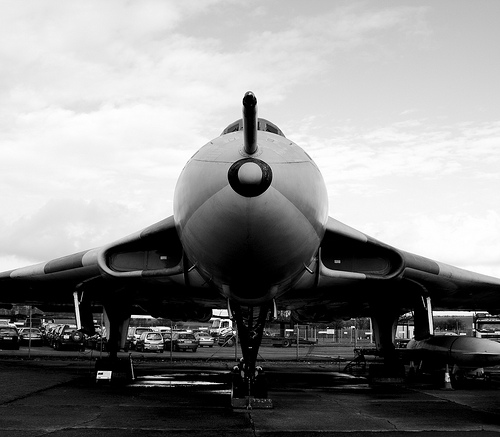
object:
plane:
[0, 92, 499, 408]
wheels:
[202, 365, 295, 398]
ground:
[3, 360, 500, 433]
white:
[152, 149, 341, 211]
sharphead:
[207, 76, 305, 218]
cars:
[171, 329, 199, 350]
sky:
[30, 17, 486, 80]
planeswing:
[326, 220, 500, 318]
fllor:
[133, 369, 226, 404]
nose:
[243, 91, 257, 151]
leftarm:
[0, 216, 189, 314]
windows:
[224, 111, 295, 134]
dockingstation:
[18, 330, 497, 396]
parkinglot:
[0, 321, 313, 354]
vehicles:
[142, 323, 198, 351]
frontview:
[432, 313, 482, 339]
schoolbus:
[391, 313, 490, 336]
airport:
[0, 240, 500, 436]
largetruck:
[212, 319, 292, 347]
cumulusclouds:
[50, 9, 221, 101]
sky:
[358, 44, 488, 97]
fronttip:
[241, 90, 258, 112]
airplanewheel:
[233, 376, 283, 409]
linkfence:
[160, 329, 208, 363]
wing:
[337, 226, 475, 288]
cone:
[442, 365, 453, 391]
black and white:
[2, 2, 499, 369]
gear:
[228, 362, 263, 408]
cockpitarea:
[217, 93, 288, 132]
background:
[0, 313, 366, 351]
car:
[142, 329, 227, 348]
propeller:
[100, 243, 183, 275]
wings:
[63, 306, 112, 340]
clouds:
[1, 40, 175, 166]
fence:
[164, 332, 360, 360]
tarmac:
[67, 397, 462, 422]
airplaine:
[0, 89, 499, 435]